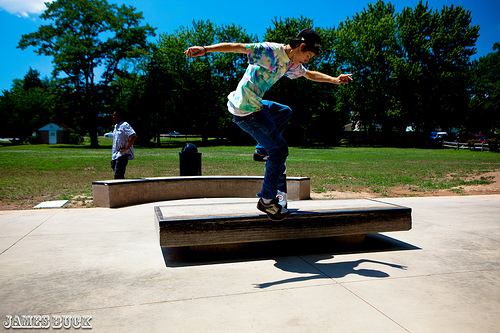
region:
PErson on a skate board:
[180, 14, 328, 251]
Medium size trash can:
[170, 132, 220, 194]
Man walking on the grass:
[94, 101, 133, 194]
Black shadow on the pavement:
[233, 241, 421, 303]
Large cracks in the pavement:
[12, 207, 63, 237]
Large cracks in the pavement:
[4, 236, 29, 266]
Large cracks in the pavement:
[8, 302, 61, 332]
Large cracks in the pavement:
[61, 282, 159, 330]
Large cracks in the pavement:
[178, 286, 298, 309]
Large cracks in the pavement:
[295, 251, 357, 307]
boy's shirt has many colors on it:
[230, 45, 305, 117]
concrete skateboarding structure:
[151, 190, 412, 249]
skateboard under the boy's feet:
[270, 161, 286, 221]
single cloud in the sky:
[4, 0, 48, 22]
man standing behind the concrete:
[107, 108, 135, 175]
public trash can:
[177, 143, 202, 173]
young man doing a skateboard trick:
[192, 28, 354, 222]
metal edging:
[159, 204, 411, 228]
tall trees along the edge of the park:
[8, 5, 495, 141]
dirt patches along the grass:
[310, 168, 498, 196]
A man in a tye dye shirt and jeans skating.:
[185, 25, 353, 221]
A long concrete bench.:
[151, 194, 415, 249]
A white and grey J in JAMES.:
[2, 313, 13, 330]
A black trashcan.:
[178, 143, 203, 177]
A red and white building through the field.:
[37, 122, 69, 147]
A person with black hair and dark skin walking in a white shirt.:
[101, 108, 135, 180]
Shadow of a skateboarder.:
[251, 247, 408, 289]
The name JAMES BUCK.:
[3, 313, 94, 329]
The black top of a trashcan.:
[181, 140, 200, 152]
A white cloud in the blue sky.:
[0, 0, 55, 20]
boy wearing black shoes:
[189, 37, 347, 217]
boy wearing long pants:
[183, 32, 350, 221]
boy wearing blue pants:
[187, 37, 356, 217]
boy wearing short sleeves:
[181, 34, 353, 218]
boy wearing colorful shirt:
[186, 32, 349, 222]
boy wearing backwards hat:
[183, 26, 358, 218]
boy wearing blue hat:
[186, 34, 347, 222]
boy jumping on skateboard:
[176, 28, 358, 225]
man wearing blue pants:
[106, 113, 139, 188]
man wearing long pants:
[105, 104, 139, 184]